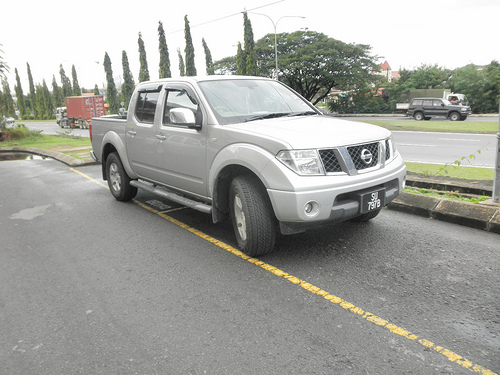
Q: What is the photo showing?
A: It is showing a city.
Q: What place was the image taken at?
A: It was taken at the city.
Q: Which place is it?
A: It is a city.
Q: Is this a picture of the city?
A: Yes, it is showing the city.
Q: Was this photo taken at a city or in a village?
A: It was taken at a city.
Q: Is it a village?
A: No, it is a city.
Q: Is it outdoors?
A: Yes, it is outdoors.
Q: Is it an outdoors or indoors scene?
A: It is outdoors.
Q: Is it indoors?
A: No, it is outdoors.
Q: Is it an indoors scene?
A: No, it is outdoors.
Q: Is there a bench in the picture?
A: No, there are no benches.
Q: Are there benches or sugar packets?
A: No, there are no benches or sugar packets.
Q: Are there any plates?
A: Yes, there is a plate.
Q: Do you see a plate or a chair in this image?
A: Yes, there is a plate.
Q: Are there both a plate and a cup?
A: No, there is a plate but no cups.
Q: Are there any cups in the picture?
A: No, there are no cups.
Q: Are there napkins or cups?
A: No, there are no cups or napkins.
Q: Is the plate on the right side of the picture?
A: Yes, the plate is on the right of the image.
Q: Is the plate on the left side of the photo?
A: No, the plate is on the right of the image.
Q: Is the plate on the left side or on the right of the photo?
A: The plate is on the right of the image.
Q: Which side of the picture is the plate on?
A: The plate is on the right of the image.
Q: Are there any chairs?
A: No, there are no chairs.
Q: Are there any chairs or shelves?
A: No, there are no chairs or shelves.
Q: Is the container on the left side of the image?
A: Yes, the container is on the left of the image.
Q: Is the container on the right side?
A: No, the container is on the left of the image.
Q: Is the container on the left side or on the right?
A: The container is on the left of the image.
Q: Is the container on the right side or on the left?
A: The container is on the left of the image.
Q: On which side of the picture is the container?
A: The container is on the left of the image.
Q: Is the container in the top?
A: Yes, the container is in the top of the image.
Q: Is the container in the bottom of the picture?
A: No, the container is in the top of the image.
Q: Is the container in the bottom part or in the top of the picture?
A: The container is in the top of the image.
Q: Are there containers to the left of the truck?
A: Yes, there is a container to the left of the truck.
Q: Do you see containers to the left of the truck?
A: Yes, there is a container to the left of the truck.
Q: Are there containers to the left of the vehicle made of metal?
A: Yes, there is a container to the left of the truck.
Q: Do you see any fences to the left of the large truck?
A: No, there is a container to the left of the truck.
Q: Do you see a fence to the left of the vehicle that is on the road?
A: No, there is a container to the left of the truck.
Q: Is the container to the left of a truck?
A: Yes, the container is to the left of a truck.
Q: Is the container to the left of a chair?
A: No, the container is to the left of a truck.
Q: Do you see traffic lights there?
A: No, there are no traffic lights.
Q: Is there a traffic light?
A: No, there are no traffic lights.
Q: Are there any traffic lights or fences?
A: No, there are no traffic lights or fences.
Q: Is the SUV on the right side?
A: Yes, the SUV is on the right of the image.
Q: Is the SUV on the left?
A: No, the SUV is on the right of the image.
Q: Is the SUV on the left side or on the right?
A: The SUV is on the right of the image.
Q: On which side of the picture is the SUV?
A: The SUV is on the right of the image.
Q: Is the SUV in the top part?
A: Yes, the SUV is in the top of the image.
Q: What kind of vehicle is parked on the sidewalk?
A: The vehicle is a SUV.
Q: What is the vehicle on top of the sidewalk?
A: The vehicle is a SUV.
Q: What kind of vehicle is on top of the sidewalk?
A: The vehicle is a SUV.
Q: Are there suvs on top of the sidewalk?
A: Yes, there is a SUV on top of the sidewalk.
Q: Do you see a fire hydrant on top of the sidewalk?
A: No, there is a SUV on top of the sidewalk.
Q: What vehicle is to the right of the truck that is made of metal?
A: The vehicle is a SUV.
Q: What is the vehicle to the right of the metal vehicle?
A: The vehicle is a SUV.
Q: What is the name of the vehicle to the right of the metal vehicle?
A: The vehicle is a SUV.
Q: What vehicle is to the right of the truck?
A: The vehicle is a SUV.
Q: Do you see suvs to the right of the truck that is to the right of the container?
A: Yes, there is a SUV to the right of the truck.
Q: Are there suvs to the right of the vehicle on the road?
A: Yes, there is a SUV to the right of the truck.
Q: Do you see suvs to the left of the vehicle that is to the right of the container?
A: No, the SUV is to the right of the truck.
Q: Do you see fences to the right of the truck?
A: No, there is a SUV to the right of the truck.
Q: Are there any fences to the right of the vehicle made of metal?
A: No, there is a SUV to the right of the truck.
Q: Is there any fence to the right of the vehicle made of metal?
A: No, there is a SUV to the right of the truck.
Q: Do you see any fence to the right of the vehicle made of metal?
A: No, there is a SUV to the right of the truck.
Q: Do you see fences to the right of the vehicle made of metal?
A: No, there is a SUV to the right of the truck.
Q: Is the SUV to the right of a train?
A: No, the SUV is to the right of a truck.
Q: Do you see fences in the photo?
A: No, there are no fences.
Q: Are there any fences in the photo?
A: No, there are no fences.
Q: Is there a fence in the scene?
A: No, there are no fences.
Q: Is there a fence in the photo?
A: No, there are no fences.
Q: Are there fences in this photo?
A: No, there are no fences.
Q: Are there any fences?
A: No, there are no fences.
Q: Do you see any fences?
A: No, there are no fences.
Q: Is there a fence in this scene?
A: No, there are no fences.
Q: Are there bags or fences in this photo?
A: No, there are no fences or bags.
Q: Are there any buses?
A: No, there are no buses.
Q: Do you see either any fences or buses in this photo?
A: No, there are no buses or fences.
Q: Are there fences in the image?
A: No, there are no fences.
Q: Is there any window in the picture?
A: Yes, there is a window.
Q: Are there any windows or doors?
A: Yes, there is a window.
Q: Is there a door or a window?
A: Yes, there is a window.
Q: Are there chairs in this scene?
A: No, there are no chairs.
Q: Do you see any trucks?
A: Yes, there is a truck.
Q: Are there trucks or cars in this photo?
A: Yes, there is a truck.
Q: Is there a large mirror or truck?
A: Yes, there is a large truck.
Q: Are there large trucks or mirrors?
A: Yes, there is a large truck.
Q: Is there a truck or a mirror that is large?
A: Yes, the truck is large.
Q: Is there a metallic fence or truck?
A: Yes, there is a metal truck.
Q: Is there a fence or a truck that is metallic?
A: Yes, the truck is metallic.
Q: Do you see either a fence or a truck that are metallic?
A: Yes, the truck is metallic.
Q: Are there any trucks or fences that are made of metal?
A: Yes, the truck is made of metal.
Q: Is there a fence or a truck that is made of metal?
A: Yes, the truck is made of metal.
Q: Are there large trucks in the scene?
A: Yes, there is a large truck.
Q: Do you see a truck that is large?
A: Yes, there is a truck that is large.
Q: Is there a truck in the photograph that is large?
A: Yes, there is a truck that is large.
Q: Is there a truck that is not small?
A: Yes, there is a large truck.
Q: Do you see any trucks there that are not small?
A: Yes, there is a large truck.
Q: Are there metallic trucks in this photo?
A: Yes, there is a metal truck.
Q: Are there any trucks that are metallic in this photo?
A: Yes, there is a metal truck.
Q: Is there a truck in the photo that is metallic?
A: Yes, there is a truck that is metallic.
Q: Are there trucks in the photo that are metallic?
A: Yes, there is a truck that is metallic.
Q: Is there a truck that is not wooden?
A: Yes, there is a metallic truck.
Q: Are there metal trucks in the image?
A: Yes, there is a truck that is made of metal.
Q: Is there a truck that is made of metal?
A: Yes, there is a truck that is made of metal.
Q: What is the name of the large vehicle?
A: The vehicle is a truck.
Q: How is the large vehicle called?
A: The vehicle is a truck.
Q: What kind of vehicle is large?
A: The vehicle is a truck.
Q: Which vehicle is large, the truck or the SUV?
A: The truck is large.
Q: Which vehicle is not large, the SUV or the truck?
A: The SUV is not large.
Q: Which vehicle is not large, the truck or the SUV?
A: The SUV is not large.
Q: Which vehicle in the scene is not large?
A: The vehicle is a SUV.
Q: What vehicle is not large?
A: The vehicle is a SUV.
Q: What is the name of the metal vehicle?
A: The vehicle is a truck.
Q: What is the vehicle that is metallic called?
A: The vehicle is a truck.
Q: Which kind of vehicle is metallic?
A: The vehicle is a truck.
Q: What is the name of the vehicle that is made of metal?
A: The vehicle is a truck.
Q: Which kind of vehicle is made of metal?
A: The vehicle is a truck.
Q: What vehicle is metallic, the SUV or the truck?
A: The truck is metallic.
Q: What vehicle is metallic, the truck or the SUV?
A: The truck is metallic.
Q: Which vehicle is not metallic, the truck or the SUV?
A: The SUV is not metallic.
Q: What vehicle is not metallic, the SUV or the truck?
A: The SUV is not metallic.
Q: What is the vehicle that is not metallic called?
A: The vehicle is a SUV.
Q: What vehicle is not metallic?
A: The vehicle is a SUV.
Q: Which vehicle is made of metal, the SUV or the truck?
A: The truck is made of metal.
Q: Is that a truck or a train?
A: That is a truck.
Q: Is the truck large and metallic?
A: Yes, the truck is large and metallic.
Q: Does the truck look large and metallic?
A: Yes, the truck is large and metallic.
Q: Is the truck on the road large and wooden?
A: No, the truck is large but metallic.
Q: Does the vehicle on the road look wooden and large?
A: No, the truck is large but metallic.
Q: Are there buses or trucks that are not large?
A: No, there is a truck but it is large.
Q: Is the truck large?
A: Yes, the truck is large.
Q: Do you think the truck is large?
A: Yes, the truck is large.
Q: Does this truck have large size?
A: Yes, the truck is large.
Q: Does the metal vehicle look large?
A: Yes, the truck is large.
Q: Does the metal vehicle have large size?
A: Yes, the truck is large.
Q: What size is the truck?
A: The truck is large.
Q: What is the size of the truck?
A: The truck is large.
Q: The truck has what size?
A: The truck is large.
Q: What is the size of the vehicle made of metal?
A: The truck is large.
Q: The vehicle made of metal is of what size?
A: The truck is large.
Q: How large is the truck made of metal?
A: The truck is large.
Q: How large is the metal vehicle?
A: The truck is large.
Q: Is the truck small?
A: No, the truck is large.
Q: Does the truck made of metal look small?
A: No, the truck is large.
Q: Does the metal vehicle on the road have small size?
A: No, the truck is large.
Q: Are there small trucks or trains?
A: No, there is a truck but it is large.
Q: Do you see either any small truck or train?
A: No, there is a truck but it is large.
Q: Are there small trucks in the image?
A: No, there is a truck but it is large.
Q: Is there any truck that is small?
A: No, there is a truck but it is large.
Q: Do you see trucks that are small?
A: No, there is a truck but it is large.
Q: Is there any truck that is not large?
A: No, there is a truck but it is large.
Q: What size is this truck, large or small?
A: The truck is large.